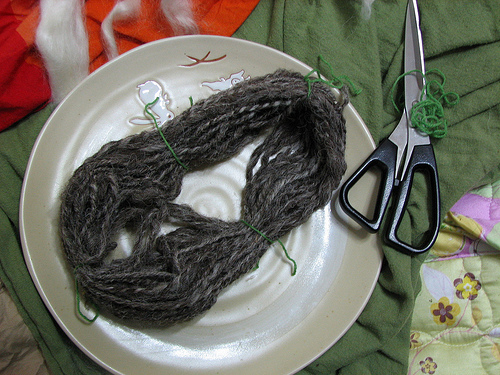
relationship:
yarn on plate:
[53, 73, 387, 324] [20, 25, 435, 360]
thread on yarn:
[142, 111, 207, 174] [53, 73, 387, 324]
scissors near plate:
[353, 1, 471, 267] [20, 25, 435, 360]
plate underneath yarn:
[20, 25, 435, 360] [53, 73, 387, 324]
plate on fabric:
[20, 25, 435, 360] [9, 4, 493, 370]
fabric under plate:
[9, 4, 493, 370] [20, 25, 435, 360]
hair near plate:
[36, 5, 211, 73] [20, 25, 435, 360]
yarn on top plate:
[53, 73, 387, 324] [20, 25, 435, 360]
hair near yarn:
[36, 5, 211, 73] [53, 73, 387, 324]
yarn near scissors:
[53, 73, 387, 324] [353, 1, 471, 267]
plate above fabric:
[20, 25, 435, 360] [9, 4, 493, 370]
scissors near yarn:
[353, 1, 471, 267] [53, 73, 387, 324]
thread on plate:
[142, 111, 207, 174] [20, 25, 435, 360]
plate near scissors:
[20, 25, 435, 360] [353, 1, 471, 267]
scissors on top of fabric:
[353, 1, 471, 267] [9, 4, 493, 370]